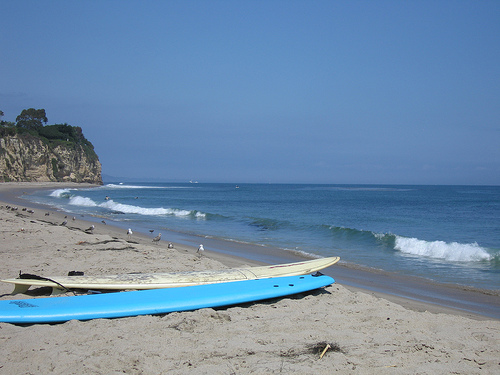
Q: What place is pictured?
A: It is a beach.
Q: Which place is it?
A: It is a beach.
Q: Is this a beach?
A: Yes, it is a beach.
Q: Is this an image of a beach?
A: Yes, it is showing a beach.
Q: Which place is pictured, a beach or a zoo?
A: It is a beach.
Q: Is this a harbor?
A: No, it is a beach.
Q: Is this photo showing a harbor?
A: No, the picture is showing a beach.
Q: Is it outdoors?
A: Yes, it is outdoors.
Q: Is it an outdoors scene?
A: Yes, it is outdoors.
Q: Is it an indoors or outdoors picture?
A: It is outdoors.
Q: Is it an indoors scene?
A: No, it is outdoors.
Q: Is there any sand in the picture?
A: Yes, there is sand.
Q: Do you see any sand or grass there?
A: Yes, there is sand.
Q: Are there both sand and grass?
A: No, there is sand but no grass.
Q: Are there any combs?
A: No, there are no combs.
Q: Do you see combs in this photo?
A: No, there are no combs.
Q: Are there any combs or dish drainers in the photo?
A: No, there are no combs or dish drainers.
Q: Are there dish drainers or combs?
A: No, there are no combs or dish drainers.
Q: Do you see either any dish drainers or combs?
A: No, there are no combs or dish drainers.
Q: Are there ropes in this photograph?
A: No, there are no ropes.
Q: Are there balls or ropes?
A: No, there are no ropes or balls.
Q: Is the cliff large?
A: Yes, the cliff is large.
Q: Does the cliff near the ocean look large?
A: Yes, the cliff is large.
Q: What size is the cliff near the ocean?
A: The cliff is large.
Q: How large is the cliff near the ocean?
A: The cliff is large.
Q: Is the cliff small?
A: No, the cliff is large.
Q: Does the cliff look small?
A: No, the cliff is large.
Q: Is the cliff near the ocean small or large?
A: The cliff is large.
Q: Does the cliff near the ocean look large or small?
A: The cliff is large.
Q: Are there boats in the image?
A: No, there are no boats.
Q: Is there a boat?
A: No, there are no boats.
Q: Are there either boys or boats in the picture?
A: No, there are no boats or boys.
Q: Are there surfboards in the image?
A: Yes, there is a surfboard.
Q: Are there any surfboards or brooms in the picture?
A: Yes, there is a surfboard.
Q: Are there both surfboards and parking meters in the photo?
A: No, there is a surfboard but no parking meters.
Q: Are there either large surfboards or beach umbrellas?
A: Yes, there is a large surfboard.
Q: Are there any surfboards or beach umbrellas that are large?
A: Yes, the surfboard is large.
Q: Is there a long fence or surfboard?
A: Yes, there is a long surfboard.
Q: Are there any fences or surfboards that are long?
A: Yes, the surfboard is long.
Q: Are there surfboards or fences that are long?
A: Yes, the surfboard is long.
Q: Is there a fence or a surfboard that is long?
A: Yes, the surfboard is long.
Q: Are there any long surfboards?
A: Yes, there is a long surfboard.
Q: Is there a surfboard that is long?
A: Yes, there is a surfboard that is long.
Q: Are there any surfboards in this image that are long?
A: Yes, there is a surfboard that is long.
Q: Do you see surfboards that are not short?
A: Yes, there is a long surfboard.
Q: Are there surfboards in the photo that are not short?
A: Yes, there is a long surfboard.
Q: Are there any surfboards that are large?
A: Yes, there is a large surfboard.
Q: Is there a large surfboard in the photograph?
A: Yes, there is a large surfboard.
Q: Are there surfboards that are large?
A: Yes, there is a surfboard that is large.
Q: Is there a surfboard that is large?
A: Yes, there is a surfboard that is large.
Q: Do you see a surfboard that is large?
A: Yes, there is a surfboard that is large.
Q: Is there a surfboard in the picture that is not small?
A: Yes, there is a large surfboard.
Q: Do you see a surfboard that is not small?
A: Yes, there is a large surfboard.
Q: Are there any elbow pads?
A: No, there are no elbow pads.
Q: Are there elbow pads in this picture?
A: No, there are no elbow pads.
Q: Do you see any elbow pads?
A: No, there are no elbow pads.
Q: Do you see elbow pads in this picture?
A: No, there are no elbow pads.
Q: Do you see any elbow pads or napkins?
A: No, there are no elbow pads or napkins.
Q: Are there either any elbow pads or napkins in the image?
A: No, there are no elbow pads or napkins.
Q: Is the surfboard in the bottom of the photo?
A: Yes, the surfboard is in the bottom of the image.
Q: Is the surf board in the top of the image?
A: No, the surf board is in the bottom of the image.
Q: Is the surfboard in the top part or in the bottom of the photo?
A: The surfboard is in the bottom of the image.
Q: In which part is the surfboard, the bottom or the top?
A: The surfboard is in the bottom of the image.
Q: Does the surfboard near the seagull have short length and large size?
A: No, the surfboard is large but long.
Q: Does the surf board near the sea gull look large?
A: Yes, the surfboard is large.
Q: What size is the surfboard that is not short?
A: The surfboard is large.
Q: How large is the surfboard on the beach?
A: The surfboard is large.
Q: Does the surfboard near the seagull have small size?
A: No, the surfboard is large.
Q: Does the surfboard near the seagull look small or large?
A: The surf board is large.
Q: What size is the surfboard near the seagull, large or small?
A: The surf board is large.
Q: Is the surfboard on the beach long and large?
A: Yes, the surfboard is long and large.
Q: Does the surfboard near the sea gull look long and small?
A: No, the surfboard is long but large.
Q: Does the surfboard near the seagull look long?
A: Yes, the surfboard is long.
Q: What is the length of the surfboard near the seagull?
A: The surfboard is long.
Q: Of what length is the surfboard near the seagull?
A: The surfboard is long.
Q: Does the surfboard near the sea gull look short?
A: No, the surfboard is long.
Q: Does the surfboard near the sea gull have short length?
A: No, the surfboard is long.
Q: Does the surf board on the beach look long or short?
A: The surfboard is long.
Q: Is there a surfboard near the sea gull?
A: Yes, there is a surfboard near the sea gull.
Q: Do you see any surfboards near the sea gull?
A: Yes, there is a surfboard near the sea gull.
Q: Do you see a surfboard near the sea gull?
A: Yes, there is a surfboard near the sea gull.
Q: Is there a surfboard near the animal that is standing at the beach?
A: Yes, there is a surfboard near the sea gull.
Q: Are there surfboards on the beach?
A: Yes, there is a surfboard on the beach.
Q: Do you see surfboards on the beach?
A: Yes, there is a surfboard on the beach.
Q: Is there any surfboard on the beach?
A: Yes, there is a surfboard on the beach.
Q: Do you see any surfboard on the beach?
A: Yes, there is a surfboard on the beach.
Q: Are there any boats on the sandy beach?
A: No, there is a surfboard on the beach.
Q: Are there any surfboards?
A: Yes, there is a surfboard.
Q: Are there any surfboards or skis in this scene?
A: Yes, there is a surfboard.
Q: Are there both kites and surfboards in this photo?
A: No, there is a surfboard but no kites.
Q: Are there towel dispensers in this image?
A: No, there are no towel dispensers.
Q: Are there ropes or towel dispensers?
A: No, there are no towel dispensers or ropes.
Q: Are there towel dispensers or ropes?
A: No, there are no towel dispensers or ropes.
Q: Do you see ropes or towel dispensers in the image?
A: No, there are no towel dispensers or ropes.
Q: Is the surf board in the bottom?
A: Yes, the surf board is in the bottom of the image.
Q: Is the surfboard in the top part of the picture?
A: No, the surfboard is in the bottom of the image.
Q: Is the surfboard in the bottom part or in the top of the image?
A: The surfboard is in the bottom of the image.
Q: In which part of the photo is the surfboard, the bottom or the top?
A: The surfboard is in the bottom of the image.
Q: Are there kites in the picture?
A: No, there are no kites.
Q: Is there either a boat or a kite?
A: No, there are no kites or boats.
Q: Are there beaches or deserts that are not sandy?
A: No, there is a beach but it is sandy.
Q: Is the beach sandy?
A: Yes, the beach is sandy.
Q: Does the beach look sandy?
A: Yes, the beach is sandy.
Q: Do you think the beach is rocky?
A: No, the beach is sandy.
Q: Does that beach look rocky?
A: No, the beach is sandy.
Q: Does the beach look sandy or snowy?
A: The beach is sandy.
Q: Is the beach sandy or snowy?
A: The beach is sandy.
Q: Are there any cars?
A: No, there are no cars.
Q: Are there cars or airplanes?
A: No, there are no cars or airplanes.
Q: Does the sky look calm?
A: Yes, the sky is calm.